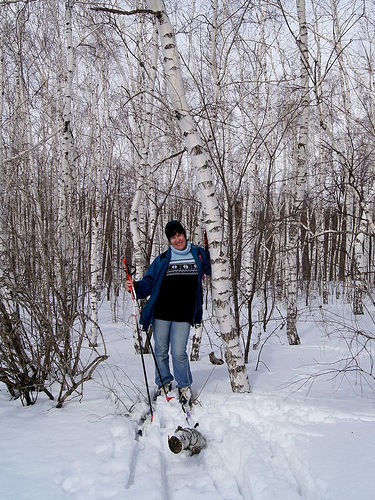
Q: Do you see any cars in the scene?
A: No, there are no cars.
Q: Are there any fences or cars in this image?
A: No, there are no cars or fences.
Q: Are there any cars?
A: No, there are no cars.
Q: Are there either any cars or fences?
A: No, there are no cars or fences.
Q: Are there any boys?
A: No, there are no boys.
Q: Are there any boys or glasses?
A: No, there are no boys or glasses.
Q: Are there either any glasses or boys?
A: No, there are no boys or glasses.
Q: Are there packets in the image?
A: No, there are no packets.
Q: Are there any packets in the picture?
A: No, there are no packets.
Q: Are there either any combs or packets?
A: No, there are no packets or combs.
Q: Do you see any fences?
A: No, there are no fences.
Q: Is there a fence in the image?
A: No, there are no fences.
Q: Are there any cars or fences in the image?
A: No, there are no fences or cars.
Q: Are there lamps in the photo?
A: No, there are no lamps.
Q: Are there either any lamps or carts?
A: No, there are no lamps or carts.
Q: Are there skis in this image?
A: Yes, there are skis.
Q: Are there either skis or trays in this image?
A: Yes, there are skis.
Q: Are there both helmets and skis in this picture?
A: No, there are skis but no helmets.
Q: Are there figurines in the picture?
A: No, there are no figurines.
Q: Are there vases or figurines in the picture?
A: No, there are no figurines or vases.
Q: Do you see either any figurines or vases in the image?
A: No, there are no figurines or vases.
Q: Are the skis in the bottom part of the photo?
A: Yes, the skis are in the bottom of the image.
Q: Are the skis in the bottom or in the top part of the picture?
A: The skis are in the bottom of the image.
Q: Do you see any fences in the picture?
A: No, there are no fences.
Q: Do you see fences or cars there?
A: No, there are no fences or cars.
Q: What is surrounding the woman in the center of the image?
A: The trees are surrounding the woman.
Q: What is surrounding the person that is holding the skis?
A: The trees are surrounding the woman.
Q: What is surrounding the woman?
A: The trees are surrounding the woman.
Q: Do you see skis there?
A: Yes, there are skis.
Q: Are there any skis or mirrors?
A: Yes, there are skis.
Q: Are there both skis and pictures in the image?
A: Yes, there are both skis and a picture.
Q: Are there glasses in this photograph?
A: No, there are no glasses.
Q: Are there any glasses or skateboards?
A: No, there are no glasses or skateboards.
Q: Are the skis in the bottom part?
A: Yes, the skis are in the bottom of the image.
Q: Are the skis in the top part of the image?
A: No, the skis are in the bottom of the image.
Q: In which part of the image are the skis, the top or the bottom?
A: The skis are in the bottom of the image.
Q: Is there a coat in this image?
A: Yes, there is a coat.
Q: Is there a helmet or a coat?
A: Yes, there is a coat.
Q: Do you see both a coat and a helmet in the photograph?
A: No, there is a coat but no helmets.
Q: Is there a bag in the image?
A: No, there are no bags.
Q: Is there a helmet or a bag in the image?
A: No, there are no bags or helmets.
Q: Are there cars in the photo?
A: No, there are no cars.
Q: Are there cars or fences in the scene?
A: No, there are no cars or fences.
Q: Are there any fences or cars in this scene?
A: No, there are no cars or fences.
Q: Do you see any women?
A: Yes, there is a woman.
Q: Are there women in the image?
A: Yes, there is a woman.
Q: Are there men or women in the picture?
A: Yes, there is a woman.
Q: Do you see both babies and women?
A: No, there is a woman but no babies.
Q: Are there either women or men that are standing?
A: Yes, the woman is standing.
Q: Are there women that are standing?
A: Yes, there is a woman that is standing.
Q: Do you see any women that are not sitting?
A: Yes, there is a woman that is standing .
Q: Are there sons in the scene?
A: No, there are no sons.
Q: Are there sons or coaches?
A: No, there are no sons or coaches.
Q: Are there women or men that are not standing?
A: No, there is a woman but she is standing.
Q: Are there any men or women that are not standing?
A: No, there is a woman but she is standing.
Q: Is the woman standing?
A: Yes, the woman is standing.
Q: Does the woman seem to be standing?
A: Yes, the woman is standing.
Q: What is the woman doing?
A: The woman is standing.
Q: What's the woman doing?
A: The woman is standing.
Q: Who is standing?
A: The woman is standing.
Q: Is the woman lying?
A: No, the woman is standing.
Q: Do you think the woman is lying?
A: No, the woman is standing.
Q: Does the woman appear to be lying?
A: No, the woman is standing.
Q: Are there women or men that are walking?
A: No, there is a woman but she is standing.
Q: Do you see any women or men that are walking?
A: No, there is a woman but she is standing.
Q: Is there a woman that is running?
A: No, there is a woman but she is standing.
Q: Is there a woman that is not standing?
A: No, there is a woman but she is standing.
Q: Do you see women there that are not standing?
A: No, there is a woman but she is standing.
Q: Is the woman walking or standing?
A: The woman is standing.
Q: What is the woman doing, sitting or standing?
A: The woman is standing.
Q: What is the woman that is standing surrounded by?
A: The woman is surrounded by the trees.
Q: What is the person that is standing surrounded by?
A: The woman is surrounded by the trees.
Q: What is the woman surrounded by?
A: The woman is surrounded by the trees.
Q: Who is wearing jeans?
A: The woman is wearing jeans.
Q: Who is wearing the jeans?
A: The woman is wearing jeans.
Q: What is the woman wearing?
A: The woman is wearing jeans.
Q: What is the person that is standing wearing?
A: The woman is wearing jeans.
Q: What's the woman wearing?
A: The woman is wearing jeans.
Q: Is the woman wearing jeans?
A: Yes, the woman is wearing jeans.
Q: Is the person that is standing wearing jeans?
A: Yes, the woman is wearing jeans.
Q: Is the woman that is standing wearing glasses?
A: No, the woman is wearing jeans.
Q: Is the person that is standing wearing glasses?
A: No, the woman is wearing jeans.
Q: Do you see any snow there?
A: Yes, there is snow.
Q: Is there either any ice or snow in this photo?
A: Yes, there is snow.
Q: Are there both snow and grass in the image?
A: No, there is snow but no grass.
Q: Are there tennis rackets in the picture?
A: No, there are no tennis rackets.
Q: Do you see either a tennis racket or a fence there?
A: No, there are no rackets or fences.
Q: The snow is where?
A: The snow is on the ground.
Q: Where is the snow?
A: The snow is on the ground.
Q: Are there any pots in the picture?
A: No, there are no pots.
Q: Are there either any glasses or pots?
A: No, there are no pots or glasses.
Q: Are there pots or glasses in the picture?
A: No, there are no pots or glasses.